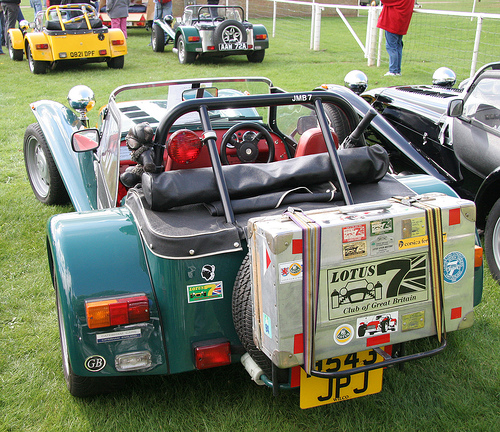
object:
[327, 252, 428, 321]
sticker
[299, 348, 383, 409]
jpj tag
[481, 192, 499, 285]
wheel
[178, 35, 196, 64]
wheel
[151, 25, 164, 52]
wheel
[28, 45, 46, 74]
wheel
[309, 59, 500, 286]
car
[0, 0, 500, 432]
ground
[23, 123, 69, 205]
front tire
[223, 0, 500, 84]
fence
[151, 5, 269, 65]
buggy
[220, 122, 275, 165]
steering wheel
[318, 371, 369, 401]
jpj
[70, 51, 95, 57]
license plate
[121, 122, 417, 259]
roll cage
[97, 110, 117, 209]
window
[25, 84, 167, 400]
side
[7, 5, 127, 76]
buggy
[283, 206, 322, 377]
strap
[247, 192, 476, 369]
suitcase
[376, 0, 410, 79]
man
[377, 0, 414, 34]
jacket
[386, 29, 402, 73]
jeans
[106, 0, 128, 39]
person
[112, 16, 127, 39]
pink pants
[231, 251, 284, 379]
spare tire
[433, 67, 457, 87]
tag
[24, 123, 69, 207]
wheel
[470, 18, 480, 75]
fence post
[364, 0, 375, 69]
fence post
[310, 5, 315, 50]
fence post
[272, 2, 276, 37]
fence post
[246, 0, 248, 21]
fence post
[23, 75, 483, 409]
buggy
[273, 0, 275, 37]
post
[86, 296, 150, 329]
light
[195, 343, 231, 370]
tail light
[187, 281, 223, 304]
signal